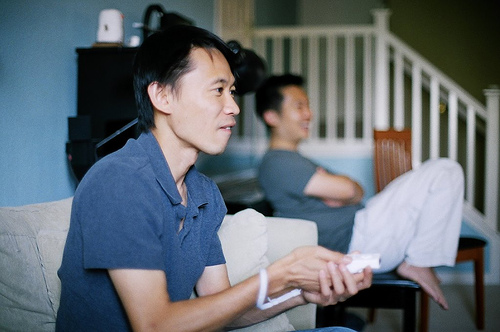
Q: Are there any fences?
A: No, there are no fences.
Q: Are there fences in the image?
A: No, there are no fences.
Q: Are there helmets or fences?
A: No, there are no fences or helmets.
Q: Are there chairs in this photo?
A: Yes, there is a chair.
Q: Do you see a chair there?
A: Yes, there is a chair.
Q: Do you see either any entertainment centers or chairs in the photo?
A: Yes, there is a chair.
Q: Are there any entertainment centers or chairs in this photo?
A: Yes, there is a chair.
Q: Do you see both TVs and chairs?
A: No, there is a chair but no televisions.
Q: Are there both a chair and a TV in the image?
A: No, there is a chair but no televisions.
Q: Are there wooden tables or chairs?
A: Yes, there is a wood chair.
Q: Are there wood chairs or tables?
A: Yes, there is a wood chair.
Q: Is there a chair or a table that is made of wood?
A: Yes, the chair is made of wood.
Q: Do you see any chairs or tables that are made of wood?
A: Yes, the chair is made of wood.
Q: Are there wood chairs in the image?
A: Yes, there is a wood chair.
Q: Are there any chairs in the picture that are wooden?
A: Yes, there is a chair that is wooden.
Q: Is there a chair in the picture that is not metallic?
A: Yes, there is a wooden chair.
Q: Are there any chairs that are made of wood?
A: Yes, there is a chair that is made of wood.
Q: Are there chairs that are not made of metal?
A: Yes, there is a chair that is made of wood.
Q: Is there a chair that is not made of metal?
A: Yes, there is a chair that is made of wood.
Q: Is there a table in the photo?
A: No, there are no tables.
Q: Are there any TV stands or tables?
A: No, there are no tables or TV stands.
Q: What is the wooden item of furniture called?
A: The piece of furniture is a chair.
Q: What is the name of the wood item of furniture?
A: The piece of furniture is a chair.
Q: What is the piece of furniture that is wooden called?
A: The piece of furniture is a chair.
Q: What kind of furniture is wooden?
A: The furniture is a chair.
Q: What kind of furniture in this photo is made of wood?
A: The furniture is a chair.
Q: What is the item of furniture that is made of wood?
A: The piece of furniture is a chair.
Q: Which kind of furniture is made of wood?
A: The furniture is a chair.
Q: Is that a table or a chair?
A: That is a chair.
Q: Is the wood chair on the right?
A: Yes, the chair is on the right of the image.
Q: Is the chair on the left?
A: No, the chair is on the right of the image.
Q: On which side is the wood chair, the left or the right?
A: The chair is on the right of the image.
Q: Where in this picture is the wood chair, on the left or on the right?
A: The chair is on the right of the image.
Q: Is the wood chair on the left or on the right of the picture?
A: The chair is on the right of the image.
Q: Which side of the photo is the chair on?
A: The chair is on the right of the image.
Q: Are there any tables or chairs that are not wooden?
A: No, there is a chair but it is wooden.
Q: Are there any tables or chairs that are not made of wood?
A: No, there is a chair but it is made of wood.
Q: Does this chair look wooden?
A: Yes, the chair is wooden.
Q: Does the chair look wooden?
A: Yes, the chair is wooden.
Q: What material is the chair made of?
A: The chair is made of wood.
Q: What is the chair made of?
A: The chair is made of wood.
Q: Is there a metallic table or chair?
A: No, there is a chair but it is wooden.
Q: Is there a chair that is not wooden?
A: No, there is a chair but it is wooden.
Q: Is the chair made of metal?
A: No, the chair is made of wood.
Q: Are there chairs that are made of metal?
A: No, there is a chair but it is made of wood.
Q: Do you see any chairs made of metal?
A: No, there is a chair but it is made of wood.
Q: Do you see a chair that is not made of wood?
A: No, there is a chair but it is made of wood.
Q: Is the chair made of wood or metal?
A: The chair is made of wood.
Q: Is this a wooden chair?
A: Yes, this is a wooden chair.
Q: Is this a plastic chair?
A: No, this is a wooden chair.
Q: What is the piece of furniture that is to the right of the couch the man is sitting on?
A: The piece of furniture is a chair.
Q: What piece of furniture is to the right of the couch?
A: The piece of furniture is a chair.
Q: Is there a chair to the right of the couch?
A: Yes, there is a chair to the right of the couch.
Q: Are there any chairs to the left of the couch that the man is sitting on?
A: No, the chair is to the right of the couch.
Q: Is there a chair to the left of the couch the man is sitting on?
A: No, the chair is to the right of the couch.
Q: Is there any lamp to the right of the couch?
A: No, there is a chair to the right of the couch.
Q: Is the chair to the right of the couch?
A: Yes, the chair is to the right of the couch.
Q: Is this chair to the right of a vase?
A: No, the chair is to the right of the couch.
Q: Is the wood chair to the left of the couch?
A: No, the chair is to the right of the couch.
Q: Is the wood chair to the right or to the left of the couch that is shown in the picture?
A: The chair is to the right of the couch.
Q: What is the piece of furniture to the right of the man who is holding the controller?
A: The piece of furniture is a chair.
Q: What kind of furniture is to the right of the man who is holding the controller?
A: The piece of furniture is a chair.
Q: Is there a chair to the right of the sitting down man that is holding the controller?
A: Yes, there is a chair to the right of the man.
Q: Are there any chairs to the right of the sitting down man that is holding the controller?
A: Yes, there is a chair to the right of the man.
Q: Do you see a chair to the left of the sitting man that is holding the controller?
A: No, the chair is to the right of the man.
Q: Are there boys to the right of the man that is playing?
A: No, there is a chair to the right of the man.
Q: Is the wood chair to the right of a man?
A: Yes, the chair is to the right of a man.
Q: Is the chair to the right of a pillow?
A: No, the chair is to the right of a man.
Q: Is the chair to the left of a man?
A: No, the chair is to the right of a man.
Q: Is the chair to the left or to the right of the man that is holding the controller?
A: The chair is to the right of the man.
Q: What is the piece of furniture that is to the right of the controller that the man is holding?
A: The piece of furniture is a chair.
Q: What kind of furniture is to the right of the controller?
A: The piece of furniture is a chair.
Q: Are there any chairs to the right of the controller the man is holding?
A: Yes, there is a chair to the right of the controller.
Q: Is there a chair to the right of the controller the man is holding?
A: Yes, there is a chair to the right of the controller.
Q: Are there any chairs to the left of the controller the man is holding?
A: No, the chair is to the right of the controller.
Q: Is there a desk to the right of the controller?
A: No, there is a chair to the right of the controller.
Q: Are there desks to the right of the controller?
A: No, there is a chair to the right of the controller.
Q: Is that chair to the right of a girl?
A: No, the chair is to the right of the controller.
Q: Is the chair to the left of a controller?
A: No, the chair is to the right of a controller.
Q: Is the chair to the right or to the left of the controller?
A: The chair is to the right of the controller.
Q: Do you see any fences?
A: No, there are no fences.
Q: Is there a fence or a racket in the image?
A: No, there are no fences or rackets.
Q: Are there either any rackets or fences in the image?
A: No, there are no fences or rackets.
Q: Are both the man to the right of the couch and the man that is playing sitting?
A: Yes, both the man and the man are sitting.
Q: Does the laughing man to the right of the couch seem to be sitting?
A: Yes, the man is sitting.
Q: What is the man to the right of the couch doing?
A: The man is sitting.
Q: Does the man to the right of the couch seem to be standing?
A: No, the man is sitting.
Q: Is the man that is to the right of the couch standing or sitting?
A: The man is sitting.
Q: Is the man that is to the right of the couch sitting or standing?
A: The man is sitting.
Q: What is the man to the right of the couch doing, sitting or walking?
A: The man is sitting.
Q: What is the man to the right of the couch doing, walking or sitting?
A: The man is sitting.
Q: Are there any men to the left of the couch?
A: No, the man is to the right of the couch.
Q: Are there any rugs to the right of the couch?
A: No, there is a man to the right of the couch.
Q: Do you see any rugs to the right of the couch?
A: No, there is a man to the right of the couch.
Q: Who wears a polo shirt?
A: The man wears a polo shirt.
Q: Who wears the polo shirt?
A: The man wears a polo shirt.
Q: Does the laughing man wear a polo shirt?
A: Yes, the man wears a polo shirt.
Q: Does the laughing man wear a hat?
A: No, the man wears a polo shirt.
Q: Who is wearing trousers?
A: The man is wearing trousers.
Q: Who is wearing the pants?
A: The man is wearing trousers.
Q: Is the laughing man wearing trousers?
A: Yes, the man is wearing trousers.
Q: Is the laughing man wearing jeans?
A: No, the man is wearing trousers.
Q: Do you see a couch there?
A: Yes, there is a couch.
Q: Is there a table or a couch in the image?
A: Yes, there is a couch.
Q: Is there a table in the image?
A: No, there are no tables.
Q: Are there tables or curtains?
A: No, there are no tables or curtains.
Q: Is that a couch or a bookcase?
A: That is a couch.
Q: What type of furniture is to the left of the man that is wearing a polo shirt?
A: The piece of furniture is a couch.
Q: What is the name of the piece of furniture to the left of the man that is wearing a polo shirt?
A: The piece of furniture is a couch.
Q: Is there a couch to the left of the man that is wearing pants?
A: Yes, there is a couch to the left of the man.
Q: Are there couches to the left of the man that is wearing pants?
A: Yes, there is a couch to the left of the man.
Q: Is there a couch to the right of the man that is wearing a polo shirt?
A: No, the couch is to the left of the man.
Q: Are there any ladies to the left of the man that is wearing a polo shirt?
A: No, there is a couch to the left of the man.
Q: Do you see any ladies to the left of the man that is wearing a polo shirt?
A: No, there is a couch to the left of the man.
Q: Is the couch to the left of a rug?
A: No, the couch is to the left of the man.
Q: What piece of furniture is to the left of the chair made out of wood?
A: The piece of furniture is a couch.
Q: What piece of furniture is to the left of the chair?
A: The piece of furniture is a couch.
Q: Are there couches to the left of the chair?
A: Yes, there is a couch to the left of the chair.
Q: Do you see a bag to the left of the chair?
A: No, there is a couch to the left of the chair.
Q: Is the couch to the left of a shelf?
A: No, the couch is to the left of the chair.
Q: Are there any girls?
A: No, there are no girls.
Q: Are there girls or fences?
A: No, there are no girls or fences.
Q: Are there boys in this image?
A: No, there are no boys.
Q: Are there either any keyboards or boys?
A: No, there are no boys or keyboards.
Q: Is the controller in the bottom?
A: Yes, the controller is in the bottom of the image.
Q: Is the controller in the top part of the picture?
A: No, the controller is in the bottom of the image.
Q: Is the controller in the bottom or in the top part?
A: The controller is in the bottom of the image.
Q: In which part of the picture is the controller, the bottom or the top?
A: The controller is in the bottom of the image.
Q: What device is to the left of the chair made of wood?
A: The device is a controller.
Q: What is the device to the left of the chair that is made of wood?
A: The device is a controller.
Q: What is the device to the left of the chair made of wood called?
A: The device is a controller.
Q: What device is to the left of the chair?
A: The device is a controller.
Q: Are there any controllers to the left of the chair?
A: Yes, there is a controller to the left of the chair.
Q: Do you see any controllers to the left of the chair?
A: Yes, there is a controller to the left of the chair.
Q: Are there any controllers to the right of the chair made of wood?
A: No, the controller is to the left of the chair.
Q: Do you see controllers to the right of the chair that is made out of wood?
A: No, the controller is to the left of the chair.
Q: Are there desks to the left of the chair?
A: No, there is a controller to the left of the chair.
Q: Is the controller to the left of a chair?
A: Yes, the controller is to the left of a chair.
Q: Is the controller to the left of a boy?
A: No, the controller is to the left of a chair.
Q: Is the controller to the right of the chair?
A: No, the controller is to the left of the chair.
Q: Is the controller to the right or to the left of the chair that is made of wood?
A: The controller is to the left of the chair.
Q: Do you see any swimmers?
A: No, there are no swimmers.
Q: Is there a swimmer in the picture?
A: No, there are no swimmers.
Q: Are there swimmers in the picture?
A: No, there are no swimmers.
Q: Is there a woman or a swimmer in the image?
A: No, there are no swimmers or women.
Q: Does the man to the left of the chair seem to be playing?
A: Yes, the man is playing.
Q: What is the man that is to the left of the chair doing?
A: The man is playing.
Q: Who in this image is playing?
A: The man is playing.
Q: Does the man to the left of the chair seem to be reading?
A: No, the man is playing.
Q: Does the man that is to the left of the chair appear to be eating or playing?
A: The man is playing.